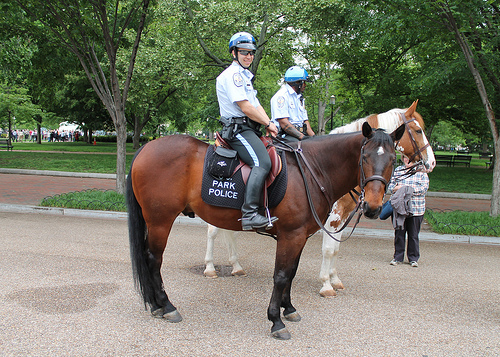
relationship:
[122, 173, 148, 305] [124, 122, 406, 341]
tail on horse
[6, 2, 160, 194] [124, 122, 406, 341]
tree behind horse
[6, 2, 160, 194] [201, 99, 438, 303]
tree behind horse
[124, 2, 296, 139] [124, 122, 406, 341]
tree behind horse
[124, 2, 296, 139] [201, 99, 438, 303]
tree behind horse